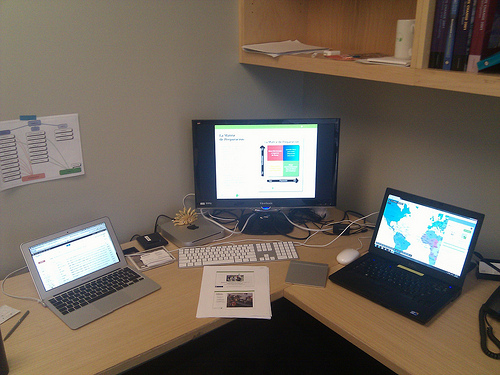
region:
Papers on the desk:
[195, 262, 270, 322]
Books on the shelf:
[425, 2, 495, 72]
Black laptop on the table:
[326, 185, 486, 324]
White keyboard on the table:
[175, 235, 297, 270]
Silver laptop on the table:
[20, 211, 161, 331]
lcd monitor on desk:
[189, 118, 341, 238]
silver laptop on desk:
[13, 213, 165, 339]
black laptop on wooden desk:
[333, 175, 487, 330]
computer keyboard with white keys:
[174, 237, 304, 267]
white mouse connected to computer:
[335, 238, 363, 265]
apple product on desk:
[158, 203, 227, 253]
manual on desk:
[200, 261, 276, 322]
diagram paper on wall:
[1, 108, 91, 185]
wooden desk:
[1, 195, 499, 374]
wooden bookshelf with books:
[236, 0, 497, 101]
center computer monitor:
[189, 113, 340, 210]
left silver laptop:
[17, 218, 159, 330]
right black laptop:
[332, 186, 485, 326]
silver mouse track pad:
[286, 255, 329, 288]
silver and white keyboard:
[178, 239, 298, 269]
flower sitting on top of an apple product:
[170, 204, 197, 227]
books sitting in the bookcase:
[427, 3, 499, 70]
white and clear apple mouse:
[335, 242, 361, 267]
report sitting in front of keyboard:
[196, 260, 271, 320]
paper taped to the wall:
[0, 113, 87, 190]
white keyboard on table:
[172, 233, 309, 272]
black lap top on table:
[315, 182, 496, 348]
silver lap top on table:
[3, 196, 161, 336]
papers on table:
[190, 247, 292, 350]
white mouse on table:
[324, 232, 366, 281]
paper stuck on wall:
[0, 99, 101, 211]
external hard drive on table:
[144, 196, 231, 257]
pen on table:
[0, 308, 51, 363]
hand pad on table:
[275, 250, 355, 301]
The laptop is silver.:
[14, 218, 160, 335]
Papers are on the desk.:
[199, 260, 267, 321]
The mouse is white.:
[335, 245, 360, 267]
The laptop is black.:
[330, 179, 484, 329]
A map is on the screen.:
[376, 193, 473, 274]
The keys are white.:
[177, 245, 307, 267]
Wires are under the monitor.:
[170, 202, 373, 241]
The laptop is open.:
[22, 227, 172, 332]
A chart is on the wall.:
[2, 111, 82, 184]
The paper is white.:
[192, 263, 272, 324]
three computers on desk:
[15, 110, 490, 336]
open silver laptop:
[8, 211, 167, 338]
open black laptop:
[325, 178, 489, 331]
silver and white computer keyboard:
[168, 235, 303, 272]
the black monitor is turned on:
[190, 118, 341, 208]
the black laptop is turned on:
[338, 188, 480, 328]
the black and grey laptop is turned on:
[20, 216, 162, 323]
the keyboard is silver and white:
[177, 240, 294, 267]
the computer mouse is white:
[336, 237, 363, 263]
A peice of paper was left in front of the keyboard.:
[195, 262, 273, 324]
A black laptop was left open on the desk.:
[319, 187, 475, 324]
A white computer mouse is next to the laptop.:
[337, 243, 359, 266]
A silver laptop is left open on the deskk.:
[14, 215, 165, 331]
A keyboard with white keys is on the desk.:
[176, 238, 302, 268]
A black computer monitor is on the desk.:
[175, 108, 338, 242]